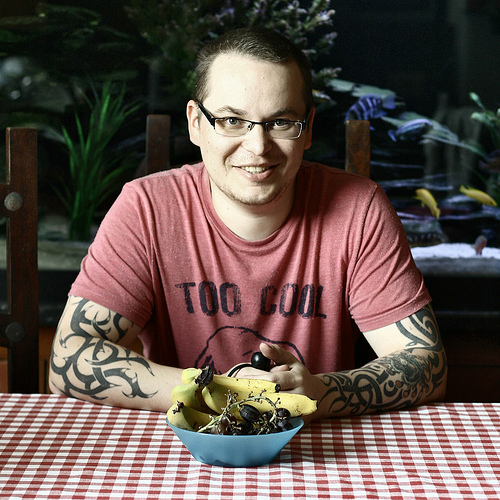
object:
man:
[49, 27, 447, 419]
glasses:
[194, 100, 311, 140]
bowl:
[169, 418, 305, 468]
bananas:
[202, 373, 317, 417]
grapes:
[221, 414, 236, 434]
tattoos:
[319, 302, 447, 413]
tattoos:
[50, 297, 158, 401]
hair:
[196, 27, 313, 111]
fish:
[387, 122, 433, 143]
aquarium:
[0, 0, 500, 275]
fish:
[345, 95, 395, 123]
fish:
[460, 188, 498, 208]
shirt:
[68, 161, 431, 372]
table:
[1, 392, 500, 499]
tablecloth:
[1, 393, 500, 500]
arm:
[309, 172, 447, 412]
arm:
[47, 179, 185, 414]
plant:
[45, 78, 145, 242]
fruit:
[167, 403, 213, 431]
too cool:
[174, 281, 327, 319]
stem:
[197, 390, 279, 435]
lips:
[234, 167, 276, 181]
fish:
[415, 189, 440, 220]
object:
[251, 352, 270, 371]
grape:
[239, 404, 260, 422]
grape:
[277, 408, 291, 421]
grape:
[277, 420, 294, 431]